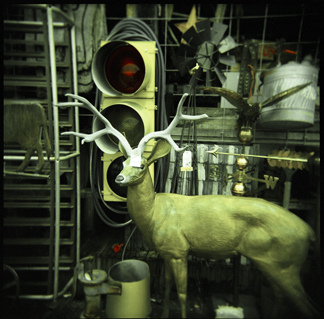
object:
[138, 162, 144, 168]
eye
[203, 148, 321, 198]
weather vane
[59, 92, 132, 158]
antler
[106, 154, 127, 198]
lights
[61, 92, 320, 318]
deer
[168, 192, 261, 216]
back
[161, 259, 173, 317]
leg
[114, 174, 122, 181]
nose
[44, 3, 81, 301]
metal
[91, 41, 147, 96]
stop light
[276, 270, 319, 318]
leg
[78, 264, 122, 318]
water pump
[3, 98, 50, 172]
cow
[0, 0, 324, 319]
garage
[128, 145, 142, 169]
tag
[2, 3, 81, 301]
metal rack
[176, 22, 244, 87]
windmill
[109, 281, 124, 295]
rust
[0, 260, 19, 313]
wheels